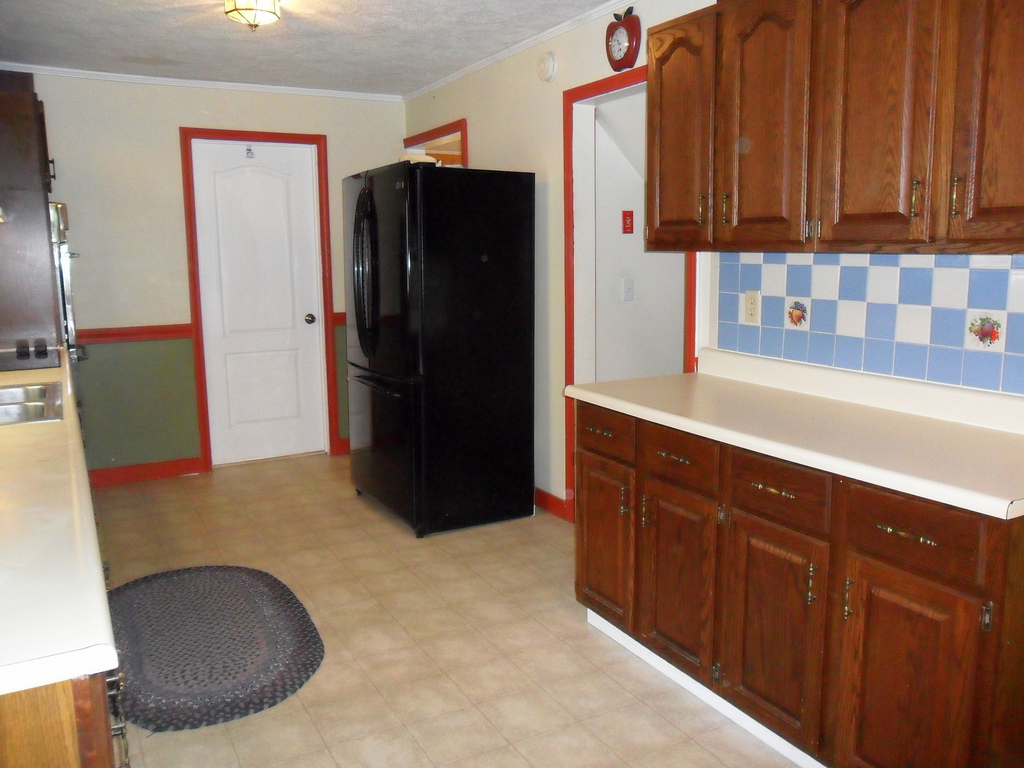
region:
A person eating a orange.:
[281, 554, 408, 709]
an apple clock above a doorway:
[593, 3, 661, 77]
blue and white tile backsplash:
[701, 247, 1022, 393]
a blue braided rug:
[107, 554, 320, 733]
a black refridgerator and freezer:
[337, 152, 560, 558]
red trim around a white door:
[167, 98, 357, 466]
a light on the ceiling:
[203, 4, 298, 49]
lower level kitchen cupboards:
[559, 369, 1015, 766]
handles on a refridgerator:
[347, 176, 383, 351]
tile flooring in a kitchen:
[356, 588, 568, 766]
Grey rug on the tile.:
[111, 543, 327, 730]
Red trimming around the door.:
[169, 116, 350, 481]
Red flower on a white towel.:
[956, 303, 1002, 364]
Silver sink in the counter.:
[0, 370, 58, 431]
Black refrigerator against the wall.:
[315, 136, 549, 554]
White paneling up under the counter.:
[567, 598, 792, 750]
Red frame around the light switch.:
[620, 192, 637, 241]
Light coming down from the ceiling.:
[219, 0, 289, 38]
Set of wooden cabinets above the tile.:
[640, 10, 1020, 252]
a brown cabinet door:
[748, 499, 791, 671]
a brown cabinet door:
[509, 426, 646, 583]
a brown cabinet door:
[649, 39, 704, 191]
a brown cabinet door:
[722, 10, 789, 182]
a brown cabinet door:
[827, 16, 879, 258]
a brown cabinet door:
[956, 37, 1020, 233]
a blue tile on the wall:
[926, 312, 988, 351]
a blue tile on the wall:
[834, 274, 874, 300]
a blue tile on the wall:
[790, 269, 822, 295]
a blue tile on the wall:
[865, 360, 870, 368]